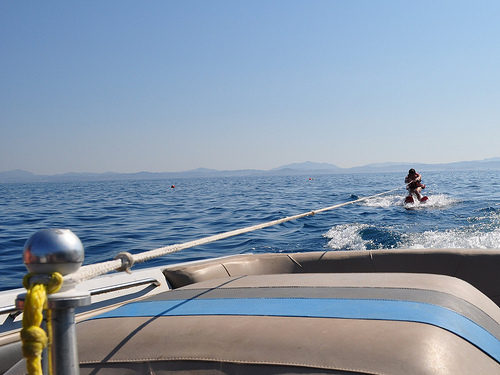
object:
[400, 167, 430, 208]
person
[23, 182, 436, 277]
rope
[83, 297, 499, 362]
strip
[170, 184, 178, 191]
buoy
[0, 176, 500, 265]
water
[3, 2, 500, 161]
sky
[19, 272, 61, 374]
rope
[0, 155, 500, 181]
mountains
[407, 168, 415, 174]
hair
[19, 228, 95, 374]
pole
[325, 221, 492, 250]
white caps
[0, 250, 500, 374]
boat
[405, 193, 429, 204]
skis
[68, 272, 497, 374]
covering